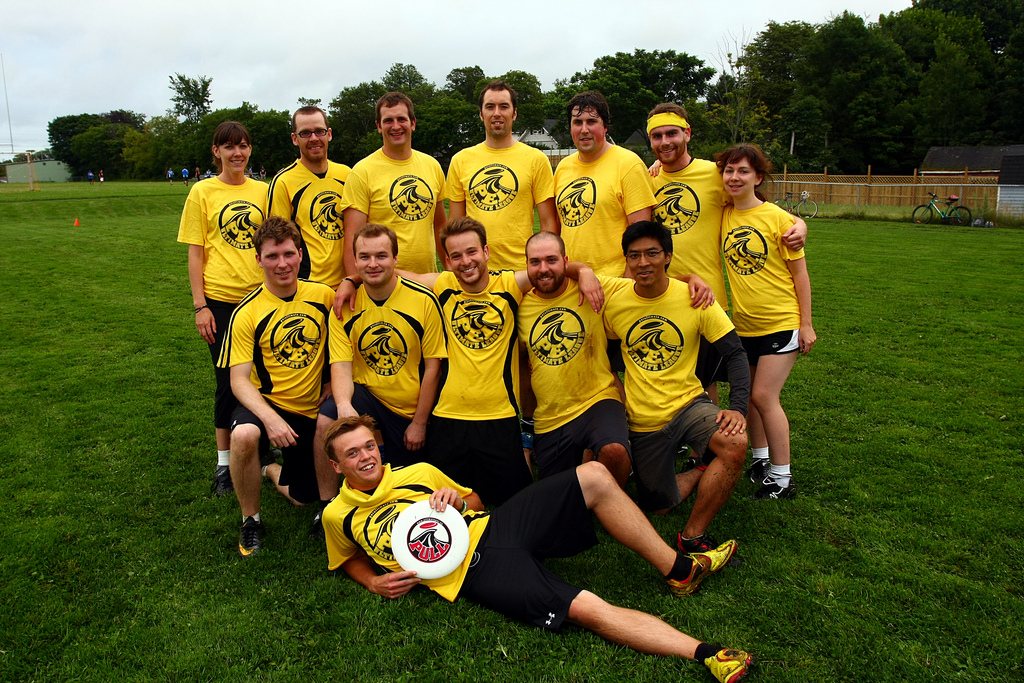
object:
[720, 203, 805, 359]
uniforms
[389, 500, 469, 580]
frisbee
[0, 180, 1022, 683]
field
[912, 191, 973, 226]
bicycle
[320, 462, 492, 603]
shirt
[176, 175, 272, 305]
shirt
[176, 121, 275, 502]
woman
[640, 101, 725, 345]
men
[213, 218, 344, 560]
men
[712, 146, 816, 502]
woman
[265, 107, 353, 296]
man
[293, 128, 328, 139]
glasses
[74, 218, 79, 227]
cone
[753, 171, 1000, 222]
fence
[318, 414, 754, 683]
boy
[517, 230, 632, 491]
man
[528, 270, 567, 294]
beard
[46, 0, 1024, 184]
trees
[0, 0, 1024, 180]
background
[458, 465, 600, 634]
shorts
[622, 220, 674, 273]
hair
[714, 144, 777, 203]
hair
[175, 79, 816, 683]
group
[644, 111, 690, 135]
headband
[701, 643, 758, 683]
shoes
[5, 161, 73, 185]
building